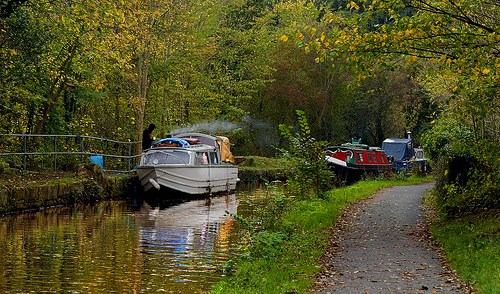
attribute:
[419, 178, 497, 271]
grass — green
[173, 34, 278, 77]
leaves — green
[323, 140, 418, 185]
boat — parked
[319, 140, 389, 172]
boat — river, red, small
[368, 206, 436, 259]
path — asphalt, paved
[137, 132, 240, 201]
boat — white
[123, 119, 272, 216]
boat — river, small, covered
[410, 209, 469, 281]
leaves — dead